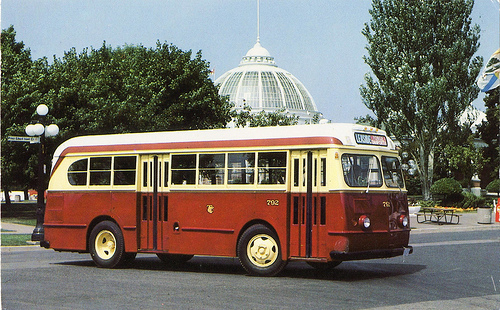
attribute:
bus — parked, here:
[40, 123, 409, 276]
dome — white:
[212, 4, 332, 124]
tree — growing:
[2, 1, 500, 203]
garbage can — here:
[478, 206, 493, 224]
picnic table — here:
[415, 205, 459, 225]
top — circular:
[240, 1, 279, 67]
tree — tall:
[355, 1, 483, 207]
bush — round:
[431, 177, 465, 208]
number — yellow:
[266, 200, 281, 207]